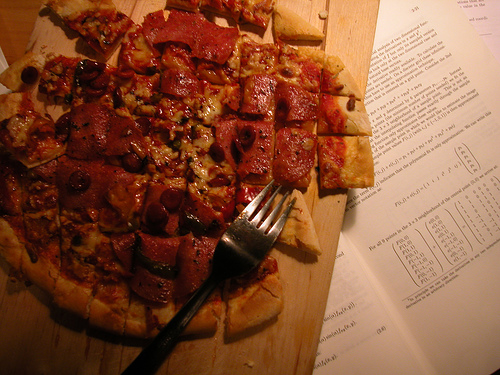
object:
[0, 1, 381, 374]
board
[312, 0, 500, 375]
paper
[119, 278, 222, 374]
handle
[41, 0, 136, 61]
piece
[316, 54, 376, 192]
edge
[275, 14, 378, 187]
crust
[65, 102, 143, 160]
pepperoni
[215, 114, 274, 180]
pepperoni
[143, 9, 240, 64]
pepperoni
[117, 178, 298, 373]
fork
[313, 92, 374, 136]
susage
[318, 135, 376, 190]
squares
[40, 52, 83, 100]
squares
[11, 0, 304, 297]
cheese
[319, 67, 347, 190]
tomatoe sauce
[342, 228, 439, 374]
crease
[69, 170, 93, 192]
olives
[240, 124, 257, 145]
olives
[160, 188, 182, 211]
olives